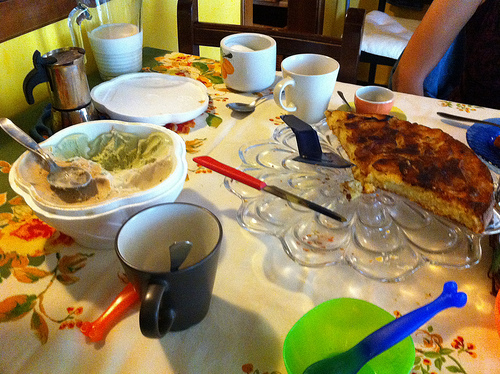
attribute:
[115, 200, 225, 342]
cup — black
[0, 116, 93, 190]
spoon — silver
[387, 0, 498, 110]
person — standing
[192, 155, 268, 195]
handle — knife, red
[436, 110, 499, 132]
handle — metal, silverware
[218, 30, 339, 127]
cups — white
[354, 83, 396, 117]
cup — orange